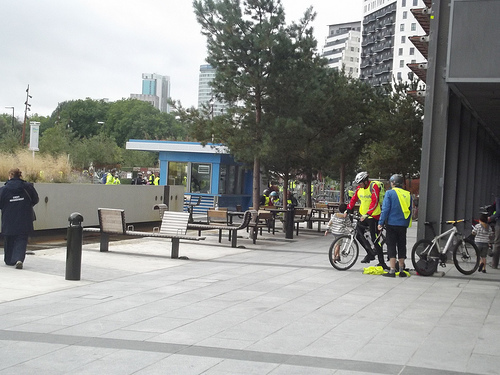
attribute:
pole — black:
[57, 206, 87, 285]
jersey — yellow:
[353, 182, 383, 222]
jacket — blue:
[377, 187, 407, 227]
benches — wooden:
[80, 219, 203, 247]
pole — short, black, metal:
[65, 209, 85, 279]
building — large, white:
[395, 29, 433, 99]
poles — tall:
[20, 86, 34, 118]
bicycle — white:
[407, 217, 488, 279]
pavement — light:
[1, 220, 498, 372]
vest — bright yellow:
[353, 184, 381, 220]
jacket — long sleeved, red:
[342, 179, 386, 216]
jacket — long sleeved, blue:
[375, 188, 417, 234]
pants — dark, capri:
[383, 223, 413, 261]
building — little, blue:
[124, 128, 272, 228]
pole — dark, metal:
[62, 207, 88, 293]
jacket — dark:
[1, 176, 44, 238]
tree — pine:
[192, 2, 312, 230]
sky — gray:
[2, 4, 361, 127]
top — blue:
[373, 184, 418, 231]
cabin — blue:
[121, 127, 263, 227]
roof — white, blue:
[129, 133, 235, 153]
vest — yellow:
[354, 182, 384, 219]